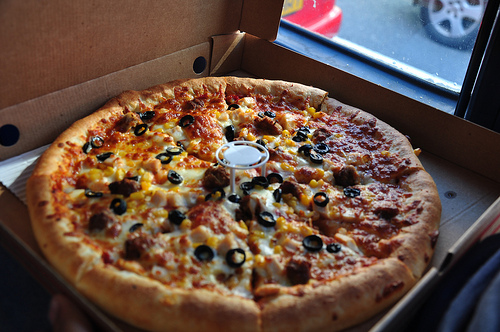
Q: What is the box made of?
A: Cardboard.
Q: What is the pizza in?
A: A box.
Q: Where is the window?
A: Behind the box.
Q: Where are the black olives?
A: On the pizza.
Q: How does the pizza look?
A: Uneaten.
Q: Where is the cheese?
A: On the pizza.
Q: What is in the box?
A: A pizza.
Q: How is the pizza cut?
A: Sliced.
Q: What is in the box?
A: The thick pizza.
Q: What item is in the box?
A: The cheesy pizza.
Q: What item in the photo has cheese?
A: The pizza.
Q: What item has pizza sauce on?
A: The pizza.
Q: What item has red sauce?
A: The pizza.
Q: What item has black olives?
A: The pizza.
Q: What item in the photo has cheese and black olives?
A: The pizza.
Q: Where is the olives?
A: On the pizza.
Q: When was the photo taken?
A: Daytime.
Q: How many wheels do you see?
A: One.